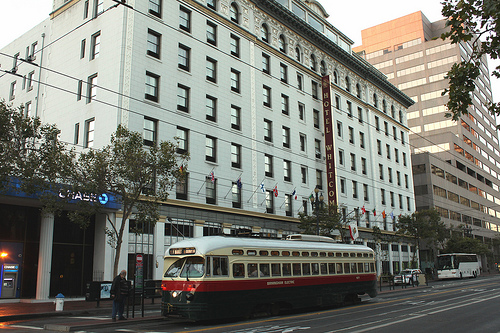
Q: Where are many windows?
A: On the buildings.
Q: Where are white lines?
A: On the road.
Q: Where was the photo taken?
A: Near a city street.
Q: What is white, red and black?
A: Train on street.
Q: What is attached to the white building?
A: Flags.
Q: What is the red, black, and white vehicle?
A: Bus.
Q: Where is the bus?
A: City street.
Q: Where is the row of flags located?
A: Alongside lower windows of white building.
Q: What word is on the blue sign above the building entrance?
A: Chase.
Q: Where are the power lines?
A: Above the street.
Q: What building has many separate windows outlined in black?
A: White building.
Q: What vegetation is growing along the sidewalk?
A: Trees.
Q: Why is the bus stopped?
A: It is parked.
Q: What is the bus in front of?
A: A building.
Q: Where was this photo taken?
A: Outside.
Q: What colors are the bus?
A: Black, red and white.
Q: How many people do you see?
A: 1.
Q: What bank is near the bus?
A: Chase.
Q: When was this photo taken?
A: During the day.